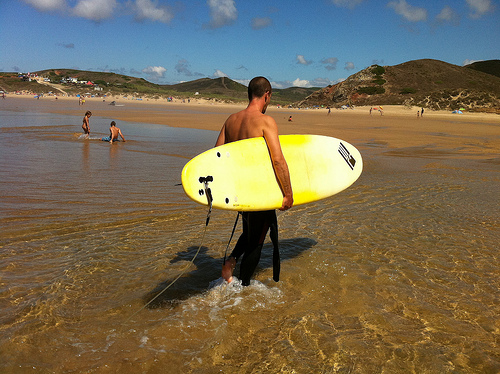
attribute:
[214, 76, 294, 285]
man — walking, light, shirtless, wading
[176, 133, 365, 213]
surfboard — yellow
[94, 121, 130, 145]
person — sitting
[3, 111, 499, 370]
water — rippled, shallow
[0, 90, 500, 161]
beach — brown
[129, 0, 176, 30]
cloud — white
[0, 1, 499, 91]
sky — blue, clear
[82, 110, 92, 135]
girl — little, playing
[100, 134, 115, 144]
shorts — blue